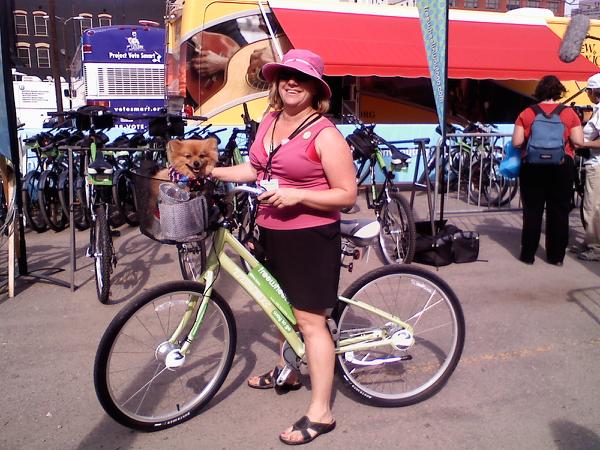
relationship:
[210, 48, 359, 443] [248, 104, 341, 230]
lady wearing shirt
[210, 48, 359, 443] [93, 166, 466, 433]
lady standing across bicycle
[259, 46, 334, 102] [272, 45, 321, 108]
hat worn on head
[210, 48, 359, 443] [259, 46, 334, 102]
lady wearing hat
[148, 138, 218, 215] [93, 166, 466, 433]
dog sitting on bicycle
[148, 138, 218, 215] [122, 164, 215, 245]
dog sitting inside basket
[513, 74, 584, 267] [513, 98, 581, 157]
lady wearing shirt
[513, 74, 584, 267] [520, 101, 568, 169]
lady carrying backpack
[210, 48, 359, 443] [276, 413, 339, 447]
lady wearing sandal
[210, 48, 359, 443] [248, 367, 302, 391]
lady wearing sandal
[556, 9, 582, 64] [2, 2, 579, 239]
sound boom hanging in background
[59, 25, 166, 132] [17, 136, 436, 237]
bus parked behind bike rack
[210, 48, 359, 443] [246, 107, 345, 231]
lady wearing top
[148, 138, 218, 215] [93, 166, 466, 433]
dog sitting on top of bicycle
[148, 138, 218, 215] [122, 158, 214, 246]
dog sitting inside basket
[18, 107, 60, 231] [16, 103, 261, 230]
bike parked in row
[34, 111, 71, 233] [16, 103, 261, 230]
bike parked in row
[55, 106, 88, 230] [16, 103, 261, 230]
bike parked in row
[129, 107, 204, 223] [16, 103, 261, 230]
bike parked in row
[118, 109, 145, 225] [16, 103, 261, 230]
bike parked in row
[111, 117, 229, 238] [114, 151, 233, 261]
dog in basket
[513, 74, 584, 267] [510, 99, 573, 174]
lady wearing back pack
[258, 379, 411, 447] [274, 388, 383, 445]
sandal on foot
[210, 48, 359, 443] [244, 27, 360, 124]
lady with hat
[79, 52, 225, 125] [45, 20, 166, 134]
grate on bus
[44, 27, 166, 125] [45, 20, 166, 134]
back of bus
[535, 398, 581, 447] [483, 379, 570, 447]
shadow on ground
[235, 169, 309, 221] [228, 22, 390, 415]
tag on lady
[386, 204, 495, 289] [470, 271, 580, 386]
luggage on ground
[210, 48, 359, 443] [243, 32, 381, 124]
lady wearing hat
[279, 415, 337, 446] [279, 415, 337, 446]
sandal on sandal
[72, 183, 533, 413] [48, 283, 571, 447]
bicycle in spot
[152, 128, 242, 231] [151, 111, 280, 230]
head of dog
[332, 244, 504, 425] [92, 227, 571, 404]
wheel of bicycle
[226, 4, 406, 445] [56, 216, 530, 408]
lady on bicycle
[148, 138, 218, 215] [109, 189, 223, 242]
dog in basket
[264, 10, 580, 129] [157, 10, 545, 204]
awning on truck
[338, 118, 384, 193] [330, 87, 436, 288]
bag on bike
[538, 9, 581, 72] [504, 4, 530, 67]
mic in air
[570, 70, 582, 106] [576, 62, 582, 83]
person wearing hat